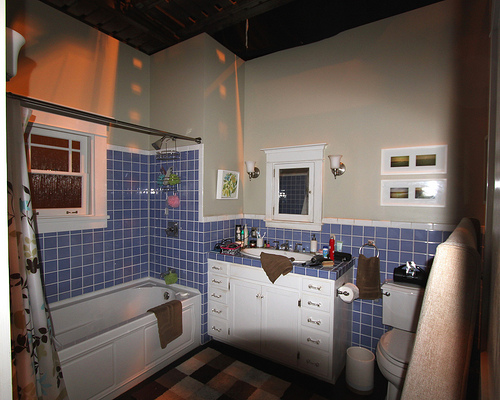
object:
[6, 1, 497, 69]
ceiling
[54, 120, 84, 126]
light